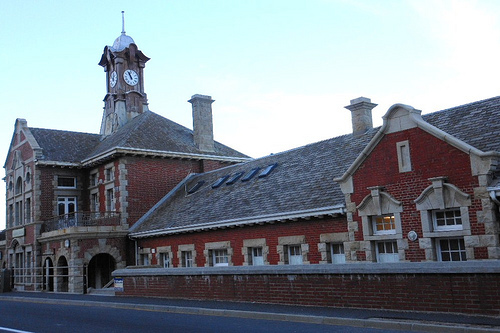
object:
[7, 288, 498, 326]
sidewalk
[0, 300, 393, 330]
black street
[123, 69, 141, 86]
clock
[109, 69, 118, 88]
clock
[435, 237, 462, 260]
window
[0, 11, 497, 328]
building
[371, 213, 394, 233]
window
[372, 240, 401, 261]
window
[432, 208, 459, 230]
window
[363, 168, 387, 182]
red brick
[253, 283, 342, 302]
wall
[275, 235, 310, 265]
window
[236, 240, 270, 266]
window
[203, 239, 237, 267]
window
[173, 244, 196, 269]
window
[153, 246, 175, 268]
window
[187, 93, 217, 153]
chimney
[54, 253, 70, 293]
entrance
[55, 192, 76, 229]
door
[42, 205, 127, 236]
balcony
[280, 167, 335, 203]
grey roof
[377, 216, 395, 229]
light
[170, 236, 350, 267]
row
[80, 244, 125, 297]
archways